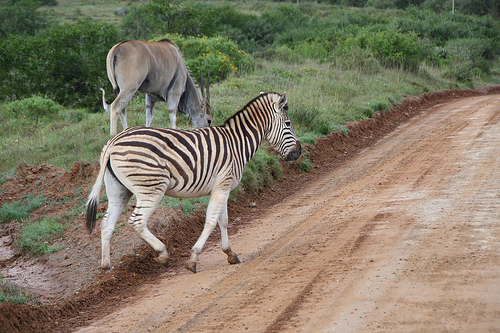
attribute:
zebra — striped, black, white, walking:
[86, 90, 302, 275]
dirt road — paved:
[51, 89, 500, 331]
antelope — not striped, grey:
[98, 38, 213, 137]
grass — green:
[1, 2, 497, 293]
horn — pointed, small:
[205, 71, 212, 106]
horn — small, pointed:
[197, 70, 205, 105]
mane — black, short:
[220, 92, 280, 124]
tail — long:
[84, 141, 115, 234]